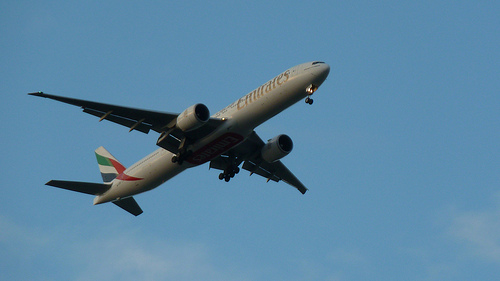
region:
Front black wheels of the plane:
[300, 93, 317, 108]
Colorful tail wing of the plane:
[87, 145, 142, 186]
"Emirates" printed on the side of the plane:
[235, 68, 294, 111]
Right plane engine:
[175, 100, 216, 135]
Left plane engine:
[260, 128, 296, 163]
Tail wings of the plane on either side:
[36, 172, 152, 222]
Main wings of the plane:
[17, 88, 315, 197]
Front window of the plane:
[309, 55, 326, 68]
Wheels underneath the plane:
[166, 150, 233, 188]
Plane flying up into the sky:
[20, 43, 355, 232]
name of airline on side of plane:
[234, 72, 296, 109]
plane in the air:
[25, 46, 422, 228]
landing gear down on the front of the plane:
[302, 88, 316, 105]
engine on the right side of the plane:
[176, 99, 208, 139]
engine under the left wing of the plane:
[256, 131, 296, 171]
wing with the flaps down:
[16, 82, 166, 144]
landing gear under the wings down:
[211, 158, 244, 194]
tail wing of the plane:
[22, 142, 162, 234]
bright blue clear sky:
[368, 8, 494, 118]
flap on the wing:
[241, 160, 281, 188]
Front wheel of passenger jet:
[298, 89, 319, 112]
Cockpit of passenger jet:
[302, 53, 335, 82]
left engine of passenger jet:
[258, 125, 302, 176]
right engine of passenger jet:
[160, 94, 216, 151]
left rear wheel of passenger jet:
[217, 156, 243, 190]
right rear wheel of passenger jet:
[163, 134, 198, 172]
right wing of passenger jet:
[23, 79, 228, 188]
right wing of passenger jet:
[218, 121, 318, 205]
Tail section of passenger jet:
[47, 137, 160, 245]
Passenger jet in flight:
[15, 43, 352, 243]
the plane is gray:
[21, 43, 349, 238]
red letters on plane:
[209, 57, 312, 123]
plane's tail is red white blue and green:
[82, 133, 135, 186]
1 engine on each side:
[162, 93, 305, 183]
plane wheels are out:
[288, 75, 324, 112]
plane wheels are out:
[213, 150, 246, 196]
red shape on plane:
[108, 168, 148, 190]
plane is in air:
[0, 22, 330, 223]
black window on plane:
[308, 55, 325, 72]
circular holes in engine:
[189, 98, 306, 160]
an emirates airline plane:
[228, 65, 310, 120]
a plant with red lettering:
[227, 72, 316, 108]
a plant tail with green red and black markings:
[93, 141, 133, 199]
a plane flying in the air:
[33, 58, 336, 213]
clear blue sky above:
[345, 92, 445, 268]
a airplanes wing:
[21, 80, 166, 135]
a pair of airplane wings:
[78, 85, 319, 177]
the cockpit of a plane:
[303, 52, 329, 68]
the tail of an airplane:
[45, 145, 148, 220]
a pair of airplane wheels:
[155, 128, 249, 178]